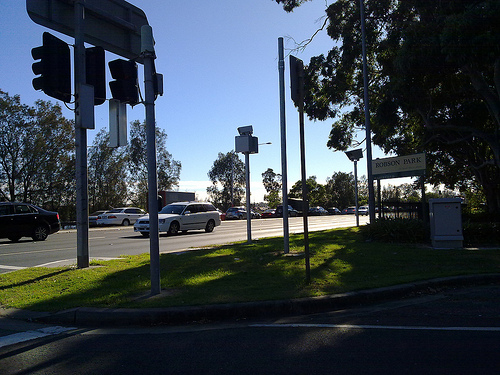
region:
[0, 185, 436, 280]
Cars driving on grey street.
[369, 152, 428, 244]
White park sign with blue lettering.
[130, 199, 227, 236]
White car is traveling on road.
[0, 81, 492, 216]
Row of trees line road.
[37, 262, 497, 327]
Grey Street Curb On Side Of Road.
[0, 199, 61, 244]
Dark Colored Car On Road.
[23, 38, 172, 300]
Street Lamp On Side Of Street.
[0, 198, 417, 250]
Cars on side of road.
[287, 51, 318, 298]
Street sign in green grass.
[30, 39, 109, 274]
Black street light on pole.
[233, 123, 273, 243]
an automatic traffic camera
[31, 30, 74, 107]
a traffic light at the intersection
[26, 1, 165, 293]
a street sign and pole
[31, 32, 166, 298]
a traffic light and post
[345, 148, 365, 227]
a traffic light camera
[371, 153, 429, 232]
an advertisement sign on the road side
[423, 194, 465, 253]
a power console box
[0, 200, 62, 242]
a black car at the intersection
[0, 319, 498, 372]
a traffic line painted on the road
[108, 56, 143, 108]
a cross walk signal light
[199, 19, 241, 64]
this is the sky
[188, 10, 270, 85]
the sky is blue in color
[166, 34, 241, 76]
the sky has clouds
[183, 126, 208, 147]
the clouds are white in color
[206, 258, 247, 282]
this is the grass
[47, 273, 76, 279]
the grass is green in color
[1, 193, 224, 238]
these are some cars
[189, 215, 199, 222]
the car is white in color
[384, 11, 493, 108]
these are some trees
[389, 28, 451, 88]
the leaves are green in color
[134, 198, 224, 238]
A white car on the road.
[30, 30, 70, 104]
A black traffic light.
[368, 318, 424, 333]
Part of a white line.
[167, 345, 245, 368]
Part of the road.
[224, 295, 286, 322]
Part of the curb.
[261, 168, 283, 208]
A tree in the distance.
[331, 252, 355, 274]
part of the grass.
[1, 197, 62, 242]
Part of a black car.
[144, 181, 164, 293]
Part of a pole.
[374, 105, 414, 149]
Part of a green tree.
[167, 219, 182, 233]
round black rubber tire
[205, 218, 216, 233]
round black rubber tire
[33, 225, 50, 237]
round black rubber tire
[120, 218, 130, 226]
round black rubber tire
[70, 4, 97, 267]
tall silver metal pole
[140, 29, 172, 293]
tall silver metal pole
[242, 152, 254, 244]
tall silver metal pole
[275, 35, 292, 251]
tall silver metal pole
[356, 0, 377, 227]
tall silver metal pole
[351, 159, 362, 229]
tall silver metal pole